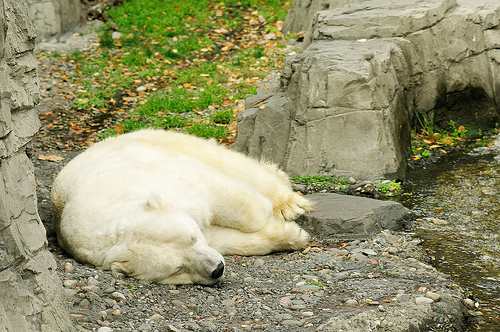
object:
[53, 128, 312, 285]
polar bear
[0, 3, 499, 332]
ground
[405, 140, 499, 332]
stream of water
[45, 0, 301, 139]
grass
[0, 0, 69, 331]
cluster of stones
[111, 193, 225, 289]
head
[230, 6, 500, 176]
rock emplacement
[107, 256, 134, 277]
right ear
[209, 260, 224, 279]
nose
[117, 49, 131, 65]
leaf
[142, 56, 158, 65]
leaf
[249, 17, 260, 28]
leaf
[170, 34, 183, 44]
leaf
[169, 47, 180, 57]
leaf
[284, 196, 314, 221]
foot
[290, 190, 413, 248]
rock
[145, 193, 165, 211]
left ear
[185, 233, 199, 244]
left eye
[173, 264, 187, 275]
right eye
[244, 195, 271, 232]
left paw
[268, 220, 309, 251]
right paw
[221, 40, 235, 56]
leaf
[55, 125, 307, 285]
fur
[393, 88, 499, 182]
crevice